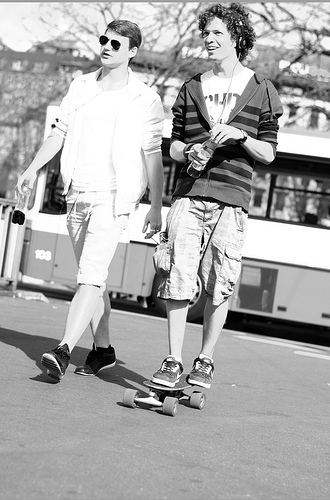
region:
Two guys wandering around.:
[11, 2, 284, 417]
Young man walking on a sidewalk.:
[15, 15, 158, 388]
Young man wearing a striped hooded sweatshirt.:
[165, 71, 285, 205]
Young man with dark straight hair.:
[88, 12, 141, 71]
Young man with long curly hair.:
[184, 0, 253, 62]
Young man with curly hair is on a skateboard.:
[118, 0, 277, 417]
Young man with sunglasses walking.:
[26, 12, 139, 398]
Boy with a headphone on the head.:
[223, 2, 246, 62]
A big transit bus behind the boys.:
[17, 95, 327, 334]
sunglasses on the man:
[97, 37, 124, 50]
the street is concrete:
[237, 442, 250, 475]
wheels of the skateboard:
[115, 388, 175, 415]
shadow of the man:
[4, 328, 53, 352]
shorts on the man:
[170, 207, 230, 304]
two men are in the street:
[36, 35, 283, 412]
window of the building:
[285, 182, 325, 218]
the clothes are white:
[95, 131, 123, 157]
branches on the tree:
[277, 14, 319, 49]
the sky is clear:
[5, 8, 47, 42]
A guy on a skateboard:
[120, 11, 275, 419]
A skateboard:
[122, 363, 206, 416]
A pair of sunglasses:
[96, 34, 125, 52]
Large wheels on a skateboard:
[122, 385, 206, 415]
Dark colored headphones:
[201, 4, 247, 70]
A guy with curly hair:
[153, 3, 241, 392]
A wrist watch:
[236, 127, 252, 148]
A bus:
[18, 102, 329, 336]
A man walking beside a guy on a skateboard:
[7, 9, 164, 385]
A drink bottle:
[177, 133, 224, 182]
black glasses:
[95, 33, 121, 53]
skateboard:
[118, 365, 213, 418]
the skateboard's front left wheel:
[160, 395, 177, 417]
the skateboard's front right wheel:
[116, 387, 140, 405]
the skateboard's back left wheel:
[187, 389, 208, 410]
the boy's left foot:
[184, 350, 217, 386]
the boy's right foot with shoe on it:
[150, 352, 186, 387]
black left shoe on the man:
[34, 343, 75, 377]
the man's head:
[95, 16, 139, 65]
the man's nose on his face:
[203, 36, 215, 42]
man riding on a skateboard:
[122, 1, 283, 415]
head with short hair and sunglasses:
[98, 19, 142, 68]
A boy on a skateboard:
[96, 352, 228, 422]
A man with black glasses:
[84, 42, 140, 63]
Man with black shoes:
[29, 347, 122, 386]